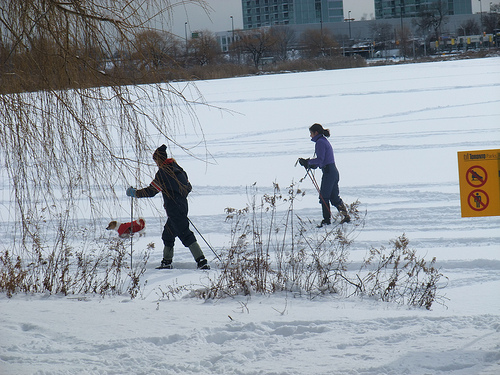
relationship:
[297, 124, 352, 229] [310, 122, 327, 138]
girl has head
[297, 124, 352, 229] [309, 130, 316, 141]
girl has face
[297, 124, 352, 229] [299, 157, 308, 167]
girl has hand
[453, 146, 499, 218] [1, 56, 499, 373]
signals in ice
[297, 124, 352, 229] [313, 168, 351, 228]
girl has legs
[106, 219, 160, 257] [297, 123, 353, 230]
dog with woman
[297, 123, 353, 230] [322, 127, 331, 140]
woman has bun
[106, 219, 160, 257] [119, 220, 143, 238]
dog has outfit